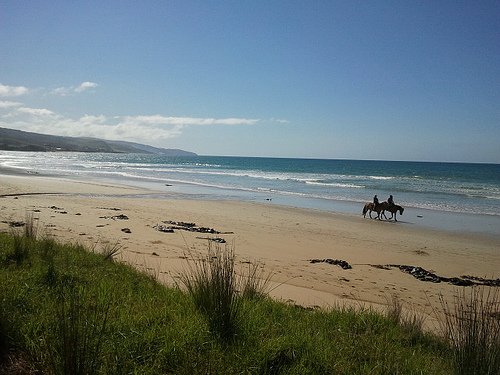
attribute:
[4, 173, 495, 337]
beach — light brown, sandy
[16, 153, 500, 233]
ocean — calm, blue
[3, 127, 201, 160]
hill — low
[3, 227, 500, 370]
area — grassy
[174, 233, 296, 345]
grass — green, clumped, tall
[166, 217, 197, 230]
rock — flat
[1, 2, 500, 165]
sky — clear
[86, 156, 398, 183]
waves — small, white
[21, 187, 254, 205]
stream — small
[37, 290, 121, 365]
grass — clumped, tall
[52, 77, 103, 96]
cloud — white